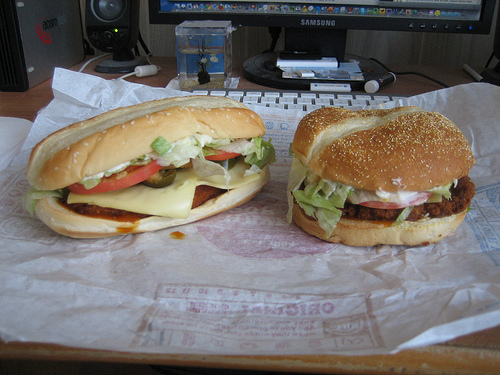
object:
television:
[143, 0, 498, 92]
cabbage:
[293, 179, 352, 239]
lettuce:
[244, 82, 285, 114]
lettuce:
[321, 228, 334, 239]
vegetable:
[292, 176, 353, 240]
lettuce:
[297, 175, 348, 232]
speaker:
[79, 5, 148, 77]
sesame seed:
[118, 123, 126, 129]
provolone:
[208, 167, 257, 189]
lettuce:
[303, 182, 332, 200]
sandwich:
[289, 104, 473, 249]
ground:
[393, 58, 420, 77]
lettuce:
[293, 178, 354, 240]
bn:
[288, 98, 478, 247]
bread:
[293, 106, 474, 194]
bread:
[289, 180, 476, 246]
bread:
[27, 94, 265, 194]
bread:
[33, 165, 270, 240]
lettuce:
[151, 136, 172, 156]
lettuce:
[244, 136, 264, 159]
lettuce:
[79, 175, 101, 189]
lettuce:
[21, 188, 64, 217]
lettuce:
[243, 154, 275, 166]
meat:
[345, 206, 429, 221]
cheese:
[65, 194, 197, 219]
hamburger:
[26, 95, 270, 239]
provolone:
[73, 188, 192, 218]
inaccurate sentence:
[171, 300, 334, 354]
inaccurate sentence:
[232, 245, 357, 314]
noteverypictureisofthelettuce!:
[276, 263, 355, 333]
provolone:
[303, 172, 348, 209]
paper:
[241, 237, 282, 275]